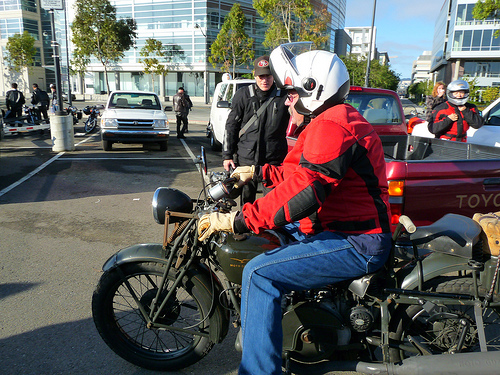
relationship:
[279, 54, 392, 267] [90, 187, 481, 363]
man on bike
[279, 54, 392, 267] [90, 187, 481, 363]
man on motorcycle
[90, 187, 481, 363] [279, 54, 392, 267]
motorcycle under man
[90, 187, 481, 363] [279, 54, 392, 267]
motorcycle below man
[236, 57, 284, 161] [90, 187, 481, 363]
man near motorcycle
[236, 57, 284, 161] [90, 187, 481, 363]
man close to motorcycle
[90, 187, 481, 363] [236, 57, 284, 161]
motorcycle near man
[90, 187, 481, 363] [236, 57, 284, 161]
motorcycle close to man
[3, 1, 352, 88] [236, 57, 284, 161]
building behind man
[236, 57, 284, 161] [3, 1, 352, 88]
man in front of building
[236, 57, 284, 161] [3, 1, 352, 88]
man beside building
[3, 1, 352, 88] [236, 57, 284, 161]
building beside man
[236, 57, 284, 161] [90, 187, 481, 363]
man on a motorcycle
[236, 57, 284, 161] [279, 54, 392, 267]
man watching man